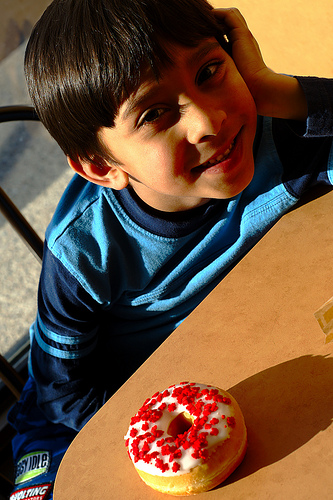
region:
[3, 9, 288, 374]
this is a child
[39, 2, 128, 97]
this is the hair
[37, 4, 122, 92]
the hair is short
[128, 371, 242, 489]
this is a doughnut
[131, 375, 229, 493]
the doughnut is creamy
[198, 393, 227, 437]
the cream is white in color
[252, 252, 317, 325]
this is a table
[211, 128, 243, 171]
this is a mouth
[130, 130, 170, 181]
the child is light skinned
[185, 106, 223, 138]
this is the nose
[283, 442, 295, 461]
[part of a shade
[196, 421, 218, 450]
part of a cream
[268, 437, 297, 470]
edge of a sajde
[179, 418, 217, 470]
part of a cream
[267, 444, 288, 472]
part of a shade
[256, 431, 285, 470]
part of a sjade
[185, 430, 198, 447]
part of a creram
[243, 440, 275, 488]
part of a sajde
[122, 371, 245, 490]
a dough nut on a table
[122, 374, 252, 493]
a dough nut with red and white icing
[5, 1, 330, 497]
a boy sitting at a table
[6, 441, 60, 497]
patches on a pair of pants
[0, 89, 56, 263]
a metal chair back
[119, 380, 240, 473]
red sprinkles on a dough nut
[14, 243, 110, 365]
a light blue strip on a shirt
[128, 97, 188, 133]
a right eye of a boy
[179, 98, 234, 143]
a nose on a boy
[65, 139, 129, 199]
a right ear on a boy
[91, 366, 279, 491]
small piece of food on table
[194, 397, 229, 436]
white frosting on donut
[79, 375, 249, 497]
donut sitting on table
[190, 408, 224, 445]
red sprinkles on donut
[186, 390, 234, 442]
sprinkles and frosting on donut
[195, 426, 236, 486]
brown and white donut on table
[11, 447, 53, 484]
patcheso n side of jacket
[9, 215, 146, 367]
blue long sleeve shirt on by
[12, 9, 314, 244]
young boy resting on hand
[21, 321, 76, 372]
light blue stripes on shirt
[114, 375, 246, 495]
A doughnut sitting on a table.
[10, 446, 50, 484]
A lime green patch on a jacket.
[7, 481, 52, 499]
A red and white patch on a jacket.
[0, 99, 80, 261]
The back of a chair.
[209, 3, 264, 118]
The left hand of a boy.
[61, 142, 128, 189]
The right ear of a boy.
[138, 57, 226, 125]
A pair of boy's eyes.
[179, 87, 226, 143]
The nose of a boy.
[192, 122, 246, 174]
A nice, wide smile of a boy.